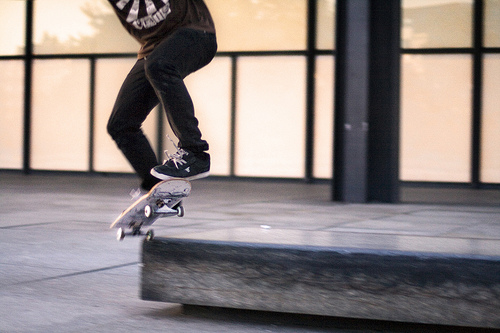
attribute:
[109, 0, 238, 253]
skateboarder — white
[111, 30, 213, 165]
black — jeans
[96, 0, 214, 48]
shirt — brown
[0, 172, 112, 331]
ground — grey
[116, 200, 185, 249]
wheels — white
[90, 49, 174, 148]
knees — bent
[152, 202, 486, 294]
concrete — grey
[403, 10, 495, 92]
frames — black